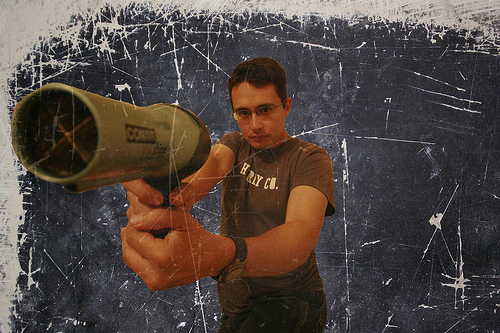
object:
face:
[229, 82, 286, 149]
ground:
[387, 149, 427, 186]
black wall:
[0, 0, 498, 331]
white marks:
[427, 211, 445, 231]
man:
[118, 57, 336, 331]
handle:
[142, 177, 180, 239]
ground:
[395, 185, 419, 208]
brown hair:
[226, 56, 286, 108]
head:
[226, 56, 293, 148]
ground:
[439, 130, 463, 151]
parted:
[243, 60, 252, 84]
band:
[212, 233, 249, 286]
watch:
[208, 232, 251, 282]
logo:
[240, 161, 280, 189]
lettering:
[267, 175, 277, 189]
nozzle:
[8, 82, 103, 184]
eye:
[238, 109, 250, 117]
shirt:
[210, 130, 337, 315]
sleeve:
[289, 143, 338, 217]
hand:
[124, 178, 194, 225]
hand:
[120, 208, 236, 292]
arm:
[215, 154, 334, 278]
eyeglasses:
[230, 101, 283, 120]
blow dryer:
[9, 81, 212, 240]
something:
[10, 81, 212, 240]